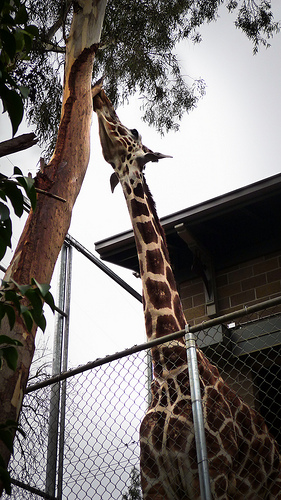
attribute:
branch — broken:
[86, 79, 108, 98]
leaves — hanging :
[150, 25, 151, 29]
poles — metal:
[57, 243, 78, 354]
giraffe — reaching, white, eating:
[93, 87, 278, 496]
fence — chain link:
[1, 370, 137, 497]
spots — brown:
[216, 418, 250, 471]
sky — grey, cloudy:
[75, 288, 125, 341]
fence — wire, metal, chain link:
[0, 287, 263, 497]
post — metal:
[182, 317, 221, 498]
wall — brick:
[218, 245, 271, 289]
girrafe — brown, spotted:
[91, 83, 280, 495]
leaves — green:
[0, 167, 63, 371]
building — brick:
[141, 245, 271, 327]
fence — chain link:
[11, 360, 260, 497]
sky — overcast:
[173, 43, 280, 168]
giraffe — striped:
[81, 118, 261, 492]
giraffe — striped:
[104, 171, 261, 484]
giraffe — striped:
[110, 226, 266, 427]